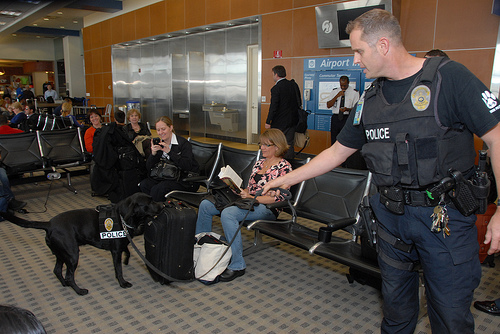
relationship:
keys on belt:
[431, 202, 450, 234] [369, 167, 495, 214]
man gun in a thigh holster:
[253, 7, 500, 334] [352, 190, 397, 250]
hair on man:
[347, 7, 401, 55] [261, 7, 499, 332]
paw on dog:
[119, 280, 134, 289] [24, 187, 171, 299]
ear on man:
[369, 35, 394, 62] [253, 7, 500, 334]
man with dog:
[253, 7, 500, 334] [8, 165, 167, 299]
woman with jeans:
[193, 125, 294, 287] [196, 193, 278, 274]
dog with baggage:
[12, 178, 184, 296] [116, 171, 212, 303]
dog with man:
[0, 192, 165, 297] [253, 7, 500, 334]